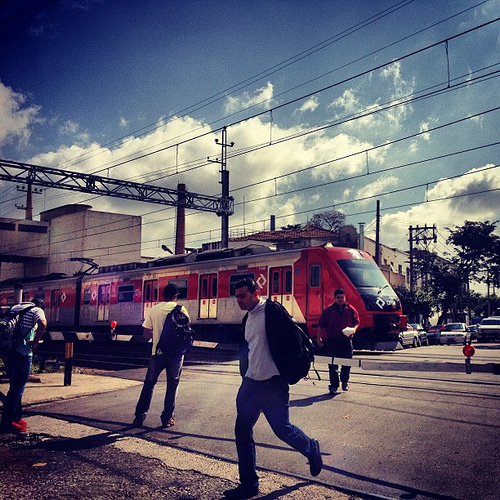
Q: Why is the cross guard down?
A: There is a train.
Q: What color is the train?
A: Red.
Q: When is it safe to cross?
A: After the train passes.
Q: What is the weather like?
A: Sunny.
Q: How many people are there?
A: 4.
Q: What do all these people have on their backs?
A: Backpacks.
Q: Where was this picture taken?
A: Downtown.